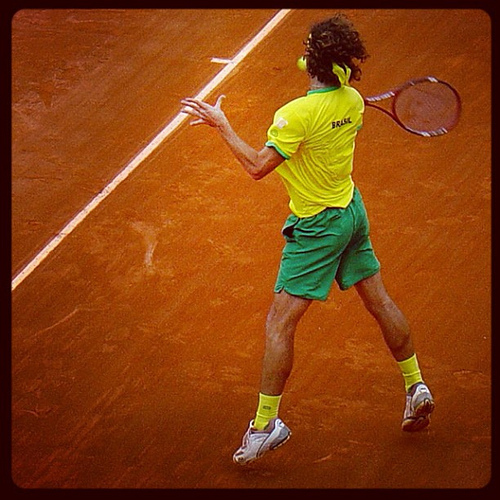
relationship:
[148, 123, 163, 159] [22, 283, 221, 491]
line painted court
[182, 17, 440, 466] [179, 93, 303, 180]
man outstretched left arm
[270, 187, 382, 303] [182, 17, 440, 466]
shorts of man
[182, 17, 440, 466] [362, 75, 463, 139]
man holding racket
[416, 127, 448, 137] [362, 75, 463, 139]
stripes on racket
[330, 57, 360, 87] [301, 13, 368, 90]
headband on head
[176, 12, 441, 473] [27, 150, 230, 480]
man standing in dirt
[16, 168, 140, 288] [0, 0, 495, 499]
line on court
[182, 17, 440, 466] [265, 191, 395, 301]
man has on shorts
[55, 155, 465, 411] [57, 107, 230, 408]
footprints on ground